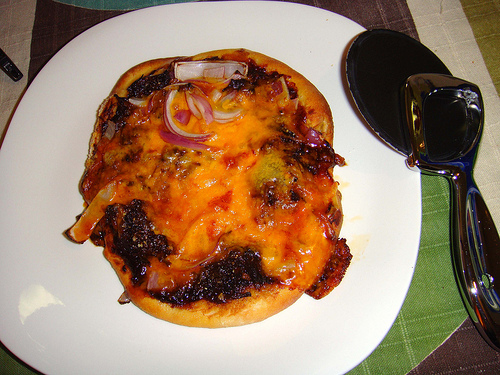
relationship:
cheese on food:
[114, 86, 331, 288] [67, 46, 354, 326]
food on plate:
[67, 46, 354, 326] [3, 0, 423, 374]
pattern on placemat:
[422, 175, 499, 292] [339, 170, 499, 371]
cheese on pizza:
[163, 91, 343, 268] [77, 39, 348, 340]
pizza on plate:
[60, 44, 355, 330] [3, 0, 423, 374]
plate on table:
[3, 0, 423, 374] [0, 3, 496, 369]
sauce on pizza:
[222, 153, 240, 165] [60, 44, 355, 330]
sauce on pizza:
[277, 212, 312, 264] [60, 44, 355, 330]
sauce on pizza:
[207, 185, 239, 221] [60, 44, 355, 330]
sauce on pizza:
[123, 103, 164, 160] [60, 44, 355, 330]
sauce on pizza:
[69, 79, 334, 289] [60, 44, 355, 330]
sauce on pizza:
[89, 186, 129, 207] [60, 44, 355, 330]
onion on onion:
[164, 89, 210, 141] [195, 100, 207, 119]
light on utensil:
[451, 277, 491, 303] [338, 9, 496, 347]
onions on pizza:
[162, 57, 246, 145] [60, 44, 355, 330]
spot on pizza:
[247, 148, 294, 199] [60, 44, 355, 330]